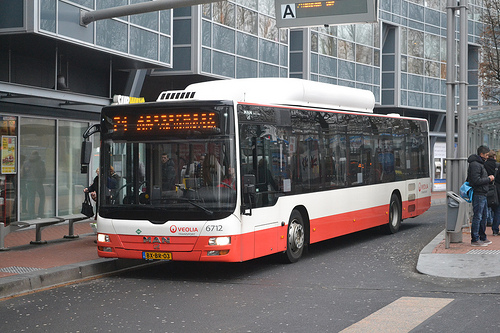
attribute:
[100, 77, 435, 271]
bus — red , white 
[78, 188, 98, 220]
purse — black 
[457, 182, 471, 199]
bag — blue 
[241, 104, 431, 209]
window — Glass 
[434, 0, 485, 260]
post — metal 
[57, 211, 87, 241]
bench — grey , concrete 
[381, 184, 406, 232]
wheel — rear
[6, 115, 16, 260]
sign — menu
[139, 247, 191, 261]
plate — yellow 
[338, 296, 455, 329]
line — white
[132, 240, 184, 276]
plate — orange 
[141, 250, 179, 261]
plate — license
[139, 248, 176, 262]
license plate — yellow , black 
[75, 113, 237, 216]
windshield — glass